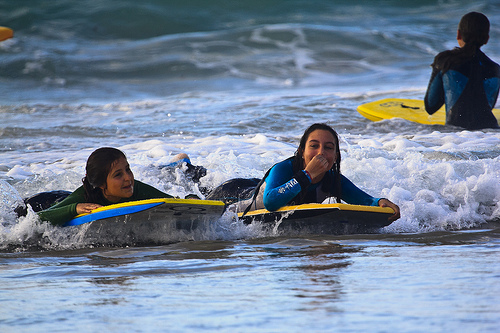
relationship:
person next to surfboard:
[433, 5, 490, 133] [347, 92, 451, 112]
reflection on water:
[268, 240, 378, 316] [57, 252, 499, 328]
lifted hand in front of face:
[300, 146, 327, 183] [285, 119, 350, 176]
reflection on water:
[0, 195, 484, 330] [277, 233, 432, 312]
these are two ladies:
[85, 139, 380, 295] [39, 113, 339, 242]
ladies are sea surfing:
[23, 123, 388, 221] [14, 21, 493, 253]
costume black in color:
[423, 44, 499, 129] [58, 161, 143, 294]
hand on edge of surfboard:
[379, 197, 401, 222] [57, 198, 225, 223]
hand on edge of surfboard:
[379, 197, 401, 222] [235, 203, 397, 230]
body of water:
[76, 159, 497, 333] [161, 48, 298, 118]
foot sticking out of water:
[166, 152, 191, 162] [0, 1, 498, 331]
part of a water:
[123, 215, 317, 333] [0, 1, 498, 331]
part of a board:
[73, 175, 236, 251] [123, 180, 224, 234]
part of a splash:
[19, 193, 61, 288] [238, 209, 385, 247]